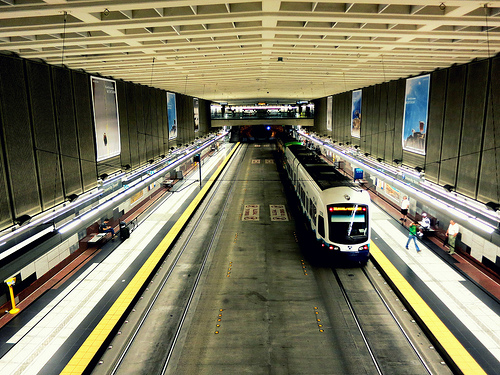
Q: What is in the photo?
A: A train.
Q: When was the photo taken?
A: Daytime.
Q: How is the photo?
A: Clear.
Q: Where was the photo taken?
A: Train station.